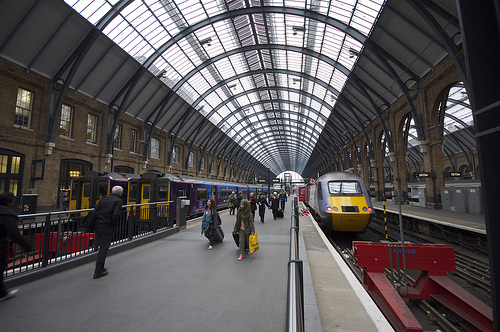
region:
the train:
[286, 154, 436, 295]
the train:
[320, 167, 366, 282]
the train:
[325, 140, 366, 235]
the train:
[310, 98, 365, 205]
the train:
[312, 105, 372, 276]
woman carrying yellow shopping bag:
[227, 196, 271, 271]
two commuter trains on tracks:
[67, 160, 267, 227]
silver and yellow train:
[303, 166, 380, 234]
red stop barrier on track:
[343, 224, 469, 329]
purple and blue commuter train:
[133, 158, 271, 218]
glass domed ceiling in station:
[119, 63, 370, 179]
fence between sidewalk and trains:
[18, 193, 202, 277]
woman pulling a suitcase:
[187, 193, 228, 250]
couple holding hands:
[251, 186, 290, 230]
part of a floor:
[184, 295, 214, 324]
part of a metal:
[279, 271, 306, 300]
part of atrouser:
[89, 230, 117, 269]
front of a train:
[324, 178, 376, 258]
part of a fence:
[136, 193, 175, 221]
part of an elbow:
[112, 205, 117, 215]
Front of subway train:
[311, 167, 376, 231]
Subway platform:
[108, 259, 348, 330]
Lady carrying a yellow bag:
[233, 196, 260, 264]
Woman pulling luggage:
[200, 194, 226, 249]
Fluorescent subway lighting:
[167, 0, 243, 83]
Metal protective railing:
[288, 260, 302, 330]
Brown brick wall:
[46, 161, 56, 206]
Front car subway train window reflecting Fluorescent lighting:
[329, 180, 359, 195]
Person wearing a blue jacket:
[278, 187, 287, 212]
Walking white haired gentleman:
[87, 184, 125, 282]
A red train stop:
[353, 237, 496, 329]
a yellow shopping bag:
[245, 224, 261, 259]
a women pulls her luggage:
[197, 197, 224, 251]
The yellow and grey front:
[321, 171, 375, 231]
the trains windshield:
[325, 177, 364, 195]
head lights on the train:
[322, 202, 376, 222]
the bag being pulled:
[273, 206, 287, 217]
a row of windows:
[10, 80, 102, 152]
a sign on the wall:
[408, 166, 440, 182]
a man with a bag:
[76, 180, 131, 285]